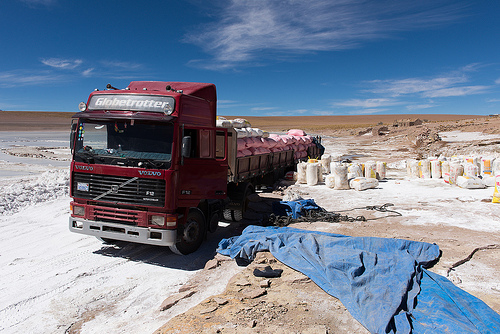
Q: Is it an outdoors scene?
A: Yes, it is outdoors.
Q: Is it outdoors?
A: Yes, it is outdoors.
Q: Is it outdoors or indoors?
A: It is outdoors.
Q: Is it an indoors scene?
A: No, it is outdoors.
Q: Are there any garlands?
A: No, there are no garlands.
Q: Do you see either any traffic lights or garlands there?
A: No, there are no garlands or traffic lights.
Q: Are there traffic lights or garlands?
A: No, there are no garlands or traffic lights.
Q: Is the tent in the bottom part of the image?
A: Yes, the tent is in the bottom of the image.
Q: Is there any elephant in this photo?
A: No, there are no elephants.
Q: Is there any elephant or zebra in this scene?
A: No, there are no elephants or zebras.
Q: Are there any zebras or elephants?
A: No, there are no elephants or zebras.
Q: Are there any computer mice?
A: No, there are no computer mice.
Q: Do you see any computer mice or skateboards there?
A: No, there are no computer mice or skateboards.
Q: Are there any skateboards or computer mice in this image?
A: No, there are no computer mice or skateboards.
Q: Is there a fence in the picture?
A: No, there are no fences.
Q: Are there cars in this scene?
A: No, there are no cars.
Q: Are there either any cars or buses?
A: No, there are no cars or buses.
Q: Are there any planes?
A: No, there are no planes.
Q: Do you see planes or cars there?
A: No, there are no planes or cars.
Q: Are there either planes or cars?
A: No, there are no planes or cars.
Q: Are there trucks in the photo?
A: Yes, there is a truck.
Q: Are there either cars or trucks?
A: Yes, there is a truck.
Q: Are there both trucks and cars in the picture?
A: No, there is a truck but no cars.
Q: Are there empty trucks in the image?
A: Yes, there is an empty truck.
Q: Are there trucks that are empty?
A: Yes, there is a truck that is empty.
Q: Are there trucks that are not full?
A: Yes, there is a empty truck.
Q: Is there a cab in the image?
A: No, there are no taxis.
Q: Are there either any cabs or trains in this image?
A: No, there are no cabs or trains.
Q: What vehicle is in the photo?
A: The vehicle is a truck.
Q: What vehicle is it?
A: The vehicle is a truck.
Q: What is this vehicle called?
A: That is a truck.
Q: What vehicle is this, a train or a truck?
A: That is a truck.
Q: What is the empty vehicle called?
A: The vehicle is a truck.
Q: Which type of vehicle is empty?
A: The vehicle is a truck.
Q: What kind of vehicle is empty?
A: The vehicle is a truck.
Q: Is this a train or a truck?
A: This is a truck.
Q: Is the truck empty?
A: Yes, the truck is empty.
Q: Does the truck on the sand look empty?
A: Yes, the truck is empty.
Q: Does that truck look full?
A: No, the truck is empty.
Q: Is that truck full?
A: No, the truck is empty.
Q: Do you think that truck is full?
A: No, the truck is empty.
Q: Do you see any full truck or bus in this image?
A: No, there is a truck but it is empty.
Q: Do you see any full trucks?
A: No, there is a truck but it is empty.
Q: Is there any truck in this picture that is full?
A: No, there is a truck but it is empty.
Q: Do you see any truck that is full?
A: No, there is a truck but it is empty.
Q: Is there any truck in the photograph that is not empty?
A: No, there is a truck but it is empty.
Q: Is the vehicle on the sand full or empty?
A: The truck is empty.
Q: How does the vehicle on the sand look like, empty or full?
A: The truck is empty.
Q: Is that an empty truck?
A: Yes, that is an empty truck.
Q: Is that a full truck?
A: No, that is an empty truck.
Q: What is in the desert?
A: The truck is in the desert.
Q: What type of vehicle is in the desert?
A: The vehicle is a truck.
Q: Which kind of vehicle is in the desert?
A: The vehicle is a truck.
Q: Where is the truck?
A: The truck is in the desert.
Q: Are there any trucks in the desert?
A: Yes, there is a truck in the desert.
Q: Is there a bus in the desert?
A: No, there is a truck in the desert.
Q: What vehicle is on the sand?
A: The vehicle is a truck.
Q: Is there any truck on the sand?
A: Yes, there is a truck on the sand.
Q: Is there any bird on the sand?
A: No, there is a truck on the sand.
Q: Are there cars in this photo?
A: No, there are no cars.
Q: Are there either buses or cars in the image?
A: No, there are no cars or buses.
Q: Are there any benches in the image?
A: No, there are no benches.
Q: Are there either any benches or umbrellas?
A: No, there are no benches or umbrellas.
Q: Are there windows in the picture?
A: Yes, there is a window.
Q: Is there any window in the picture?
A: Yes, there is a window.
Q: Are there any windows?
A: Yes, there is a window.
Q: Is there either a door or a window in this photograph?
A: Yes, there is a window.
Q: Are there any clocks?
A: No, there are no clocks.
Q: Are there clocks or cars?
A: No, there are no clocks or cars.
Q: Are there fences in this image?
A: No, there are no fences.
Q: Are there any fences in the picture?
A: No, there are no fences.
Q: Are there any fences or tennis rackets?
A: No, there are no fences or tennis rackets.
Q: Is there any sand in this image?
A: Yes, there is sand.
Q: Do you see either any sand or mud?
A: Yes, there is sand.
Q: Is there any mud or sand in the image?
A: Yes, there is sand.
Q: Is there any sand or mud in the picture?
A: Yes, there is sand.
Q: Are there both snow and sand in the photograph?
A: No, there is sand but no snow.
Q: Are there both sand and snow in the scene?
A: No, there is sand but no snow.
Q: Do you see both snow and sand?
A: No, there is sand but no snow.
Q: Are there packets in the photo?
A: No, there are no packets.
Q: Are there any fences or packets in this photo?
A: No, there are no packets or fences.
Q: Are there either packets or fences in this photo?
A: No, there are no packets or fences.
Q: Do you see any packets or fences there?
A: No, there are no packets or fences.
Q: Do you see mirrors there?
A: Yes, there is a mirror.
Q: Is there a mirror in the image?
A: Yes, there is a mirror.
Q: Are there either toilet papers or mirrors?
A: Yes, there is a mirror.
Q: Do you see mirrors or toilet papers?
A: Yes, there is a mirror.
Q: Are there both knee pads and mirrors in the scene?
A: No, there is a mirror but no knee pads.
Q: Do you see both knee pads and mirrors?
A: No, there is a mirror but no knee pads.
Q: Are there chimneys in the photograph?
A: No, there are no chimneys.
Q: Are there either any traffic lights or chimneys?
A: No, there are no chimneys or traffic lights.